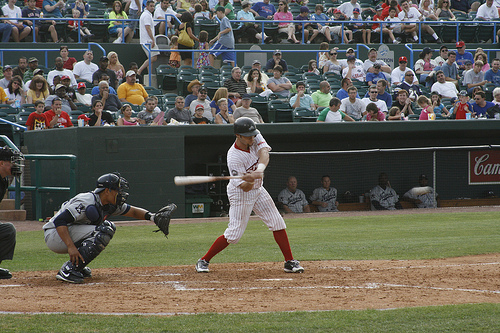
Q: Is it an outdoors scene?
A: Yes, it is outdoors.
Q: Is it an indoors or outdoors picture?
A: It is outdoors.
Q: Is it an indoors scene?
A: No, it is outdoors.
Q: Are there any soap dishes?
A: No, there are no soap dishes.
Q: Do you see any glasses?
A: No, there are no glasses.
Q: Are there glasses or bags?
A: No, there are no glasses or bags.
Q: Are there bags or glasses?
A: No, there are no glasses or bags.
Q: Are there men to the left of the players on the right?
A: Yes, there is a man to the left of the players.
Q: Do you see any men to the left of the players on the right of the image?
A: Yes, there is a man to the left of the players.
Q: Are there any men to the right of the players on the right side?
A: No, the man is to the left of the players.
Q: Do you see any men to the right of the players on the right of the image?
A: No, the man is to the left of the players.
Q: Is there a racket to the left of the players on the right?
A: No, there is a man to the left of the players.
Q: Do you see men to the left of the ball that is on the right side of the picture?
A: Yes, there is a man to the left of the ball.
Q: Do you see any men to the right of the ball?
A: No, the man is to the left of the ball.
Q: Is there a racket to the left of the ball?
A: No, there is a man to the left of the ball.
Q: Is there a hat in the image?
A: Yes, there is a hat.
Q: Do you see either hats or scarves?
A: Yes, there is a hat.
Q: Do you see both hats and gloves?
A: Yes, there are both a hat and gloves.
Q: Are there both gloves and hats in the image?
A: Yes, there are both a hat and gloves.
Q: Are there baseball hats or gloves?
A: Yes, there is a baseball hat.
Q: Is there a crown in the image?
A: No, there are no crowns.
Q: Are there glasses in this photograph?
A: No, there are no glasses.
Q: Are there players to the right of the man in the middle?
A: Yes, there are players to the right of the man.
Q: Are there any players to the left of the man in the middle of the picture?
A: No, the players are to the right of the man.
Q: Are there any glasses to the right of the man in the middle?
A: No, there are players to the right of the man.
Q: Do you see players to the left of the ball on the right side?
A: Yes, there are players to the left of the ball.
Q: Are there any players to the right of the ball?
A: No, the players are to the left of the ball.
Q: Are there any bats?
A: Yes, there is a bat.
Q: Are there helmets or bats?
A: Yes, there is a bat.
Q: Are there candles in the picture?
A: No, there are no candles.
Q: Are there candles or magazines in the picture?
A: No, there are no candles or magazines.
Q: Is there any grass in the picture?
A: Yes, there is grass.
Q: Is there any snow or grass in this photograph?
A: Yes, there is grass.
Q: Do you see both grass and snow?
A: No, there is grass but no snow.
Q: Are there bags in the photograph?
A: No, there are no bags.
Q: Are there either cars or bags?
A: No, there are no bags or cars.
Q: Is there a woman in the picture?
A: Yes, there is a woman.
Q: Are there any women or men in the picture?
A: Yes, there is a woman.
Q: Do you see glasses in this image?
A: No, there are no glasses.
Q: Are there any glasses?
A: No, there are no glasses.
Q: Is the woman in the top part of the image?
A: Yes, the woman is in the top of the image.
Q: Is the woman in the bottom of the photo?
A: No, the woman is in the top of the image.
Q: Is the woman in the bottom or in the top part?
A: The woman is in the top of the image.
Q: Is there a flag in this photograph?
A: No, there are no flags.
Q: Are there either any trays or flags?
A: No, there are no flags or trays.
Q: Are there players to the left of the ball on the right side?
A: Yes, there are players to the left of the ball.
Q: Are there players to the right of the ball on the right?
A: No, the players are to the left of the ball.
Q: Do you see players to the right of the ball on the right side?
A: No, the players are to the left of the ball.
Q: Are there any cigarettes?
A: No, there are no cigarettes.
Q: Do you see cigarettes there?
A: No, there are no cigarettes.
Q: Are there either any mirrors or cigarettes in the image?
A: No, there are no cigarettes or mirrors.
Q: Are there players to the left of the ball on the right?
A: Yes, there are players to the left of the ball.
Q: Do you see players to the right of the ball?
A: No, the players are to the left of the ball.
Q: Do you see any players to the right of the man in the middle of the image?
A: Yes, there are players to the right of the man.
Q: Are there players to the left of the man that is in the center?
A: No, the players are to the right of the man.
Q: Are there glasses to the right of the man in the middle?
A: No, there are players to the right of the man.